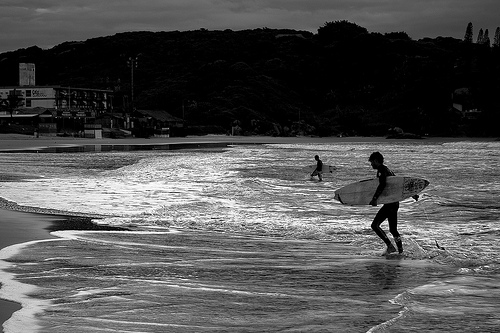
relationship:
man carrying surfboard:
[368, 150, 419, 256] [335, 175, 428, 208]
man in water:
[368, 150, 419, 256] [6, 135, 495, 329]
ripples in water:
[0, 142, 499, 332] [411, 155, 482, 275]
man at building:
[368, 150, 419, 256] [0, 62, 172, 138]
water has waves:
[82, 142, 499, 330] [227, 202, 379, 253]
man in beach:
[368, 150, 419, 256] [2, 132, 486, 326]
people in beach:
[308, 154, 322, 182] [2, 132, 486, 326]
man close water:
[368, 150, 419, 256] [6, 135, 495, 329]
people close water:
[310, 155, 324, 182] [6, 135, 495, 329]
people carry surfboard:
[310, 155, 324, 182] [332, 175, 429, 205]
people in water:
[310, 155, 324, 182] [113, 154, 465, 261]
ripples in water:
[0, 142, 499, 332] [6, 135, 495, 329]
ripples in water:
[0, 142, 499, 332] [195, 142, 492, 261]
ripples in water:
[379, 284, 417, 329] [6, 135, 495, 329]